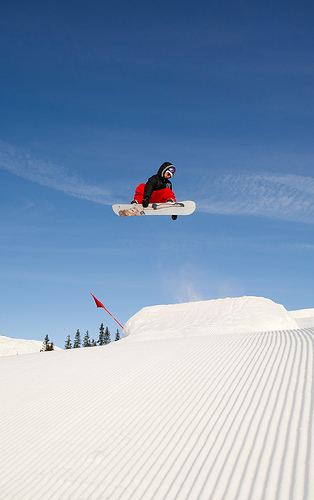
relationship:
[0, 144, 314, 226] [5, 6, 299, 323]
clouds in sky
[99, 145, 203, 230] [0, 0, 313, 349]
man in air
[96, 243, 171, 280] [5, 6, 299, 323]
clouds in sky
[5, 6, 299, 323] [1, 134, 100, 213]
sky in clouds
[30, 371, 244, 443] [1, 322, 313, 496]
snow on side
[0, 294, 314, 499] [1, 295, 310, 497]
snow on side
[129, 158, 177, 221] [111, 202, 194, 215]
man on snowboard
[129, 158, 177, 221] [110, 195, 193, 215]
man on snowboard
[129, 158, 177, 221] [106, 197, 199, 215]
man on snowboard